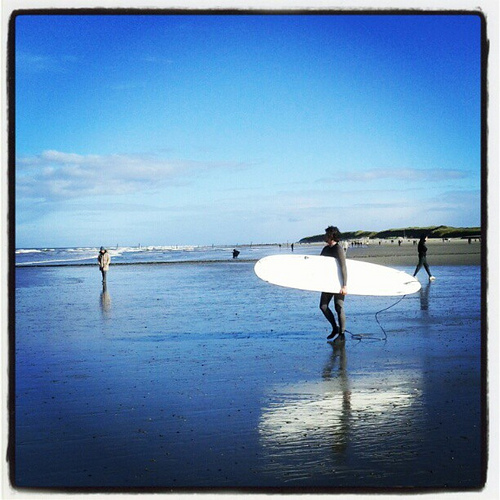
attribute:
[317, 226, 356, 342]
surfer — walking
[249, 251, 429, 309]
surfboard — white, long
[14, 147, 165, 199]
cloud — white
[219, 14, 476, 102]
sky — blue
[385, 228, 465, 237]
mountain — distant, ranged, green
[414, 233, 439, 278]
person — walking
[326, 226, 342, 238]
hair — dark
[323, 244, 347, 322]
wetsuit — dark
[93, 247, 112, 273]
person — standing, walking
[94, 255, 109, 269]
jacket — gray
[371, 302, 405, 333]
rope — black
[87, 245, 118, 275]
woman — standing, looking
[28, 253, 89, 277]
waves — white, crashing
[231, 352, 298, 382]
water — shallow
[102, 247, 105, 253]
hat — blue